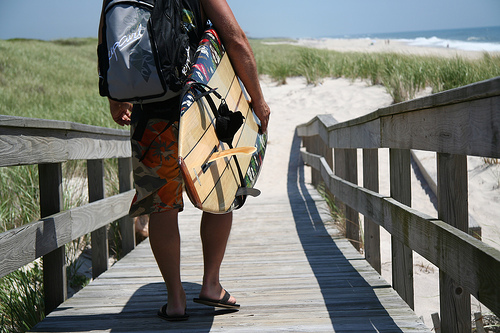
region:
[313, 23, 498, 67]
The water is blue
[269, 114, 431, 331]
There are shadows on the bridge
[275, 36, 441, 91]
The sand is white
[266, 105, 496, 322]
The bridge is made of wood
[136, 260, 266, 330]
The man is wearing flip flops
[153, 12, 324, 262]
A multi colored surf board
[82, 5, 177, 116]
A black back pack with white writing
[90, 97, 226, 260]
Orange print swim trunks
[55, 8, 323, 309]
A man carrying a surf board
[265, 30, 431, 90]
Tall green grass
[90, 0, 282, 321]
A surfer coming down a ramp towards the ocean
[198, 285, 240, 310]
sandle on man's foot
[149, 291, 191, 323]
sandle on the man's foot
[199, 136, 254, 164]
fin on the surfboard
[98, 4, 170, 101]
back pack on man's back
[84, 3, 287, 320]
man holding surf board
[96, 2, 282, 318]
man walking to the beach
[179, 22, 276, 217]
surfboard in man's hand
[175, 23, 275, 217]
colorful surfboard in man's hand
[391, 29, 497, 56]
waves on the beach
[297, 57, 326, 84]
grass near the sand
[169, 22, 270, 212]
a multicolored wooden surfboard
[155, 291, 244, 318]
flip flops on a man's feet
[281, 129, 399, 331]
the shadow of a fence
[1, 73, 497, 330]
a wooden foot bridge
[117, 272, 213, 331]
the shadow from the surfboard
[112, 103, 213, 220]
tropical style shorts on a man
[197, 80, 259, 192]
black binding on a surfboard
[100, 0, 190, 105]
a gray and black backpack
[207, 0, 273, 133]
a man's right tan arm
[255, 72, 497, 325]
white sand on the beach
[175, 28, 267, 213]
a wooden surfboard under the man's arm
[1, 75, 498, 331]
a wooden walkway bridge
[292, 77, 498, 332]
wooden side to the bridge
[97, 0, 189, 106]
a black and gray packback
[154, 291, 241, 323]
a pair of black sandals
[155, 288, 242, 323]
men's black beach sandals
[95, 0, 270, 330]
a man walking across a bridge to the beach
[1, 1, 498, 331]
a man carrying a wooden surfboard to the beach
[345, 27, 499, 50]
people in the water on the beach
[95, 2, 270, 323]
a young man going to the beach to surfboard